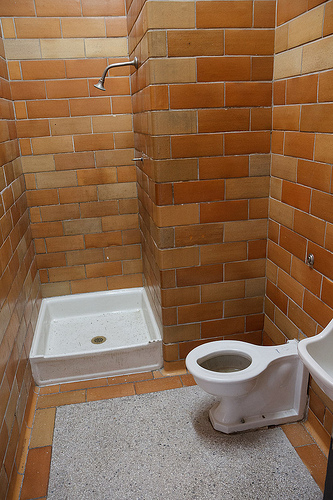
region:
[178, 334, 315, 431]
white toilet seat in room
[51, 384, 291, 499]
grey floor by toilet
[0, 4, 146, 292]
brown brick in shower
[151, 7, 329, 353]
brown brick by toilet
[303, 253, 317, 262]
grey wall mount above toilet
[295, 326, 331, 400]
white sink by toilet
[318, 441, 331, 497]
black pole under sink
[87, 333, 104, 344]
drain in shower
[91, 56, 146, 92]
silver shower head in shower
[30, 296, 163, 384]
white bottom of shower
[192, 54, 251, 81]
tile in the bathroom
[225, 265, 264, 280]
tile in the bathroom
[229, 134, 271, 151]
tile in the bathroom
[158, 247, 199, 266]
tile in the bathroom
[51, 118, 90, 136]
tile in the bathroom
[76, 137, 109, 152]
tile in the bathroom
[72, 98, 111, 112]
tile in the bathroom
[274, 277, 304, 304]
tile in the bathroom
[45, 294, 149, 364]
a shower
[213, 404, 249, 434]
bottom of the toilet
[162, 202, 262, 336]
the wall is made of bricks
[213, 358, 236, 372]
inside of the toilet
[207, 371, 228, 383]
the toilet seat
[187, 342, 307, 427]
the toilet is white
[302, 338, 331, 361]
a sink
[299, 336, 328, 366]
the sink is white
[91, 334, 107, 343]
a drain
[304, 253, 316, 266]
a button on the wall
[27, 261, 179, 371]
the shower is on ground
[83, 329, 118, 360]
drain in the shower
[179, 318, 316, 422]
toilet attached to wall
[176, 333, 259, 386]
hole in the toilet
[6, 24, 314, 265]
wall made of brick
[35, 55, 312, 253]
the wall is orange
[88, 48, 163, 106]
shower head on the wall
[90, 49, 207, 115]
the shower is silver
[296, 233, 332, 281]
button on the wall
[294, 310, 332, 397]
sink attached to wall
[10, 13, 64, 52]
tan and brown tiles on bathroom wall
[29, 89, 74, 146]
tan and brown tiles on bathroom wall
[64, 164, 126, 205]
tan and brown tiles on bathroom wall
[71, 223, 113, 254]
tan and brown tiles on bathroom wall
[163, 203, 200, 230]
tan and brown tiles on bathroom wall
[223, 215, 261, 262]
tan and brown tiles on bathroom wall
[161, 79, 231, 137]
tan and brown tiles on bathroom wall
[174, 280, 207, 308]
tan and brown tiles on bathroom wall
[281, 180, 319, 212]
tan and brown tiles on bathroom wall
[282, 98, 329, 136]
tan and brown tiles on bathroom wall